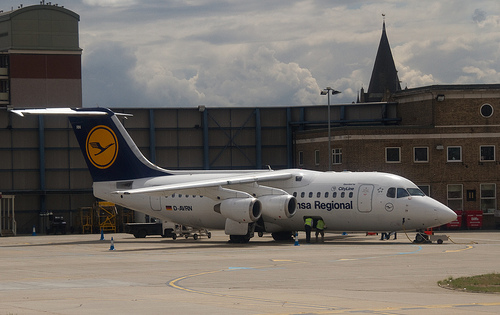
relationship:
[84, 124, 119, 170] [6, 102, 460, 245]
logo on plane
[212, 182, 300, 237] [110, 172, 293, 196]
engines under wing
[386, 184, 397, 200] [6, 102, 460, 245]
window on plane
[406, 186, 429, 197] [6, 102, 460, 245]
windshield on plane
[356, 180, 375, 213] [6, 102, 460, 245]
door on plane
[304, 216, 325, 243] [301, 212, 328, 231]
workers in luggage compartment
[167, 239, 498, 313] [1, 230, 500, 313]
lines on tarmac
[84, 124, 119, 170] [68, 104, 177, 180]
circle on tail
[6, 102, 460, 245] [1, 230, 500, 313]
plane on tarmac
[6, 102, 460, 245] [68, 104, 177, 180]
plane has tail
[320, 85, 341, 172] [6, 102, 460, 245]
light pole beyond plane